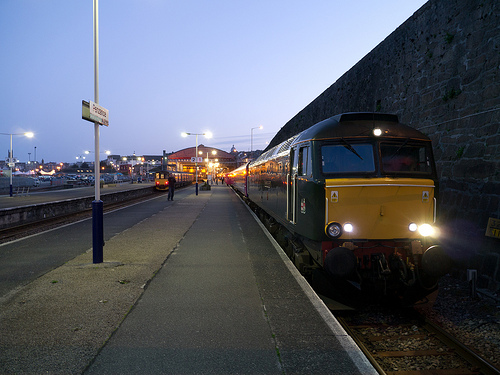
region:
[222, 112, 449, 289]
a train is on the tracks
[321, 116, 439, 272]
lights are on the front of the train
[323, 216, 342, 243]
one light on the front of the train is not on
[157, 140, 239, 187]
the train station is next to the tracks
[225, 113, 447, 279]
the train is pulling passenger cars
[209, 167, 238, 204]
people are waiting to board the train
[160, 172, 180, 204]
a man is standing alone near the tracks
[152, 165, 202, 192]
a train is leaving the station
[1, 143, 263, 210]
the city in is the background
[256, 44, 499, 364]
a stone wall is next to the train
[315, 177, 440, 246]
yellow front of a train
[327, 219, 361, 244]
an unlit headlight next to a smaller lit light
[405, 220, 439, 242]
a bright headlight next to a smaller light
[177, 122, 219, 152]
a brightly lit street light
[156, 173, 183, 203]
a man standing on the sidewalk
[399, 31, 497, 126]
a rock wall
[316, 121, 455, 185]
the front two windows of the train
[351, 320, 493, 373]
train tracks with gravel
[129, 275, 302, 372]
a sidewalk alongside the train track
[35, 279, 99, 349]
an area of dead grass between two sidewalks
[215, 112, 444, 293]
a long train on the track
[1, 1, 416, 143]
the blue sky above the track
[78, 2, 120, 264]
a pole in the middle of the platform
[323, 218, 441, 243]
the lights on the train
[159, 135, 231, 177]
a building in the background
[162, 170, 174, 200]
a man standing on the platform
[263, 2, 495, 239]
a wall next to the train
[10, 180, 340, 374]
a platform in the middle of the train station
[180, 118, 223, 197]
a line of light poles in the middle of the platform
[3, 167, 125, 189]
a parking lot next to the train tracks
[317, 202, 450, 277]
The train lights are on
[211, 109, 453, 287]
The train is yellow, green, black and red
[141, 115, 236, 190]
The train station has a red roof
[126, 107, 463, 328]
One train has left the station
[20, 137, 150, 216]
A parking lot is full of cars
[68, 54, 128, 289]
A white and blue sign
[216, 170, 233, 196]
A person waits at the station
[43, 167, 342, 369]
The divider between both tracks is made out of cement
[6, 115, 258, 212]
Multiple white street lights are on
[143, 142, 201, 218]
A train is at the station with red lights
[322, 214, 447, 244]
lights turned on in front of train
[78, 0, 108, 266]
blue and white sign post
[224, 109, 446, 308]
yellow and black passenger train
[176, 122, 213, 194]
street light illuminated with two lamps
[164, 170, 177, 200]
person in black waiting for train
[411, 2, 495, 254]
tall brick wall beside train tracks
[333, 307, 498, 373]
steel passenger train tracks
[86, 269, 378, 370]
grey concrete train platform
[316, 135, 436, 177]
two large windows on front of train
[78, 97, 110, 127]
white sign with red letters